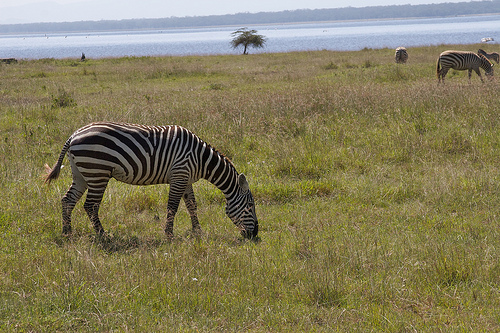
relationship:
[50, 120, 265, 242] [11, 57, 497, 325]
zebra in field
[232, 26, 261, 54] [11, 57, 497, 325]
tree in field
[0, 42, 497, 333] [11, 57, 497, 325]
field in field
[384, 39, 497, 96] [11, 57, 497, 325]
zebras in field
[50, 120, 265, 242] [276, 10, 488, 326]
zebra facing right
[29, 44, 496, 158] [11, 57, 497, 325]
herd in field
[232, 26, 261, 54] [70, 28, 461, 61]
tree along shore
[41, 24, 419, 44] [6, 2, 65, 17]
water reflecting sun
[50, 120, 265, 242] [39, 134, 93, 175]
zebra has tail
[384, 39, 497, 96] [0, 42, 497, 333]
zebras in field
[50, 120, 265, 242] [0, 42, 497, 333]
zebra eats field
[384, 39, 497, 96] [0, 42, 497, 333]
zebras eating field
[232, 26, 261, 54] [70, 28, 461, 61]
tree by shore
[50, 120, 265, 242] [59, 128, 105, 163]
zebra has butt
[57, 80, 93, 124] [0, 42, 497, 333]
bush in field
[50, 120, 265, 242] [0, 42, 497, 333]
zebra on field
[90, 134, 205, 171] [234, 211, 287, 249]
striped zebra eating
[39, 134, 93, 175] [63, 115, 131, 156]
tail on back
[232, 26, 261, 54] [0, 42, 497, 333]
tree on field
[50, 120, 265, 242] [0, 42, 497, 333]
zebra eating field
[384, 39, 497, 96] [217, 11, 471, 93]
zebras in background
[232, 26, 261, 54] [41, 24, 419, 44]
tree by water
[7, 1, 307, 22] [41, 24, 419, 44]
sky behind water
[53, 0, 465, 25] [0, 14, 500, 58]
land behind water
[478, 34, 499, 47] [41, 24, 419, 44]
rock in water